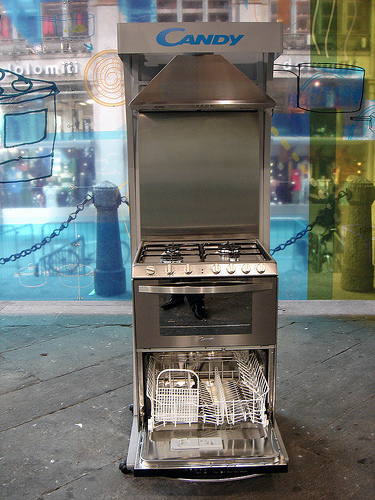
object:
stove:
[137, 236, 279, 285]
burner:
[141, 243, 201, 258]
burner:
[199, 252, 275, 262]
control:
[145, 265, 156, 275]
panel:
[133, 265, 278, 276]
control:
[162, 267, 176, 276]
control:
[184, 264, 192, 274]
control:
[211, 266, 223, 276]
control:
[224, 265, 238, 275]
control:
[240, 267, 252, 278]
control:
[254, 266, 267, 276]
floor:
[7, 303, 371, 499]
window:
[156, 284, 251, 335]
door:
[131, 280, 277, 348]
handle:
[139, 287, 279, 297]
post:
[86, 179, 127, 299]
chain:
[2, 188, 350, 260]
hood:
[131, 49, 274, 237]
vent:
[134, 94, 263, 114]